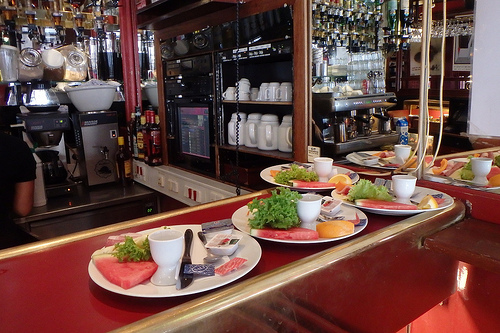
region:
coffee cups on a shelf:
[220, 78, 292, 104]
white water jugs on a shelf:
[253, 110, 276, 160]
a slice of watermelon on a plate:
[90, 256, 153, 288]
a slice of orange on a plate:
[318, 211, 358, 246]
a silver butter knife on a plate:
[178, 222, 198, 300]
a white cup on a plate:
[155, 222, 184, 285]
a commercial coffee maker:
[80, 116, 122, 201]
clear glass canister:
[57, 45, 86, 82]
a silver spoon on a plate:
[196, 223, 213, 269]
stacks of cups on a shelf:
[227, 71, 262, 105]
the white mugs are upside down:
[221, 75, 295, 105]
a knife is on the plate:
[177, 223, 197, 288]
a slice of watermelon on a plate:
[89, 249, 157, 288]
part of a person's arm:
[3, 131, 40, 220]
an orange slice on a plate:
[312, 216, 354, 239]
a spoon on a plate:
[195, 229, 225, 264]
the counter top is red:
[3, 180, 466, 331]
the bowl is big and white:
[65, 83, 121, 113]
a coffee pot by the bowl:
[19, 108, 86, 206]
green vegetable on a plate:
[246, 184, 302, 229]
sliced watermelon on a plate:
[82, 256, 159, 297]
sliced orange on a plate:
[315, 211, 364, 251]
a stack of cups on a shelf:
[233, 67, 255, 100]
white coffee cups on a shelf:
[259, 76, 292, 106]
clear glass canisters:
[16, 47, 88, 77]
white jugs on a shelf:
[249, 108, 279, 160]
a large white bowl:
[55, 74, 120, 129]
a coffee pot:
[27, 116, 128, 217]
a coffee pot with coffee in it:
[15, 78, 57, 120]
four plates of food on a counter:
[79, 152, 434, 328]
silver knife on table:
[168, 226, 199, 311]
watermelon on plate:
[80, 226, 179, 306]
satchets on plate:
[177, 251, 264, 283]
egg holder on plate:
[120, 199, 197, 316]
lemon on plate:
[324, 162, 351, 192]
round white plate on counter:
[85, 215, 294, 313]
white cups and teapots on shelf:
[183, 45, 300, 177]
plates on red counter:
[42, 120, 485, 308]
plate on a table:
[79, 202, 254, 319]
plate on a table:
[227, 182, 377, 266]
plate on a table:
[346, 178, 454, 240]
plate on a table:
[249, 138, 360, 202]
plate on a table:
[337, 125, 431, 177]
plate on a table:
[435, 148, 499, 196]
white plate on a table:
[85, 212, 269, 304]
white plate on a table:
[226, 173, 373, 255]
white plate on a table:
[329, 165, 461, 233]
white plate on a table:
[243, 143, 364, 204]